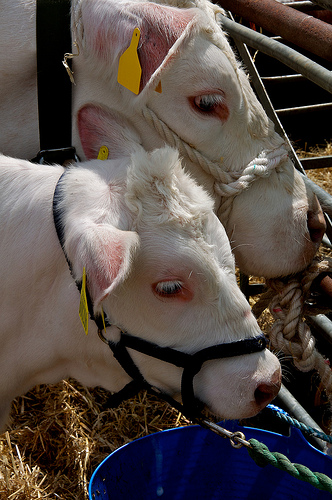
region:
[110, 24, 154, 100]
tag in the ear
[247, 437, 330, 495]
the rope is green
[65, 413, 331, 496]
blue bucket on the ground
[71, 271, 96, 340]
yellow and black tag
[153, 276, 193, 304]
pink circle around the eye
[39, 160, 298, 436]
black straps around the head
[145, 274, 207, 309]
eye on the side of the head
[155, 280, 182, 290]
white eyelashes on the eye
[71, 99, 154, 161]
pink and white ear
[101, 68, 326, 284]
rope around the head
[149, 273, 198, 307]
pink ring around the eye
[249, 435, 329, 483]
the rope is gren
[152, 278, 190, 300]
white eyelashes on the eye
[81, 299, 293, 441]
black straps around the face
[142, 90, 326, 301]
rope around the face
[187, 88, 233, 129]
eye on the side of the head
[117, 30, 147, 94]
yellow tag in the ear